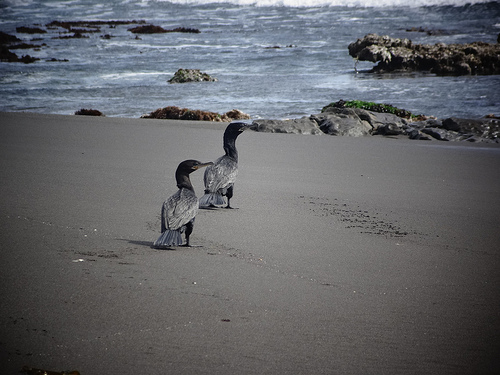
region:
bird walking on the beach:
[152, 160, 209, 250]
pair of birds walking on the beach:
[152, 120, 258, 250]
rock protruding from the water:
[167, 64, 217, 84]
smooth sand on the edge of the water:
[0, 107, 499, 373]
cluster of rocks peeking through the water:
[0, 18, 201, 66]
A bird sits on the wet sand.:
[201, 122, 253, 210]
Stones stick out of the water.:
[348, 33, 498, 75]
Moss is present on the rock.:
[323, 98, 426, 119]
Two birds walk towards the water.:
[152, 120, 253, 245]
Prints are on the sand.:
[301, 193, 406, 235]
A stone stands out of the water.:
[169, 68, 214, 83]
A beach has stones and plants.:
[1, 0, 498, 129]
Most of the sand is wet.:
[1, 112, 493, 373]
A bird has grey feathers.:
[156, 160, 212, 252]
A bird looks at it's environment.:
[155, 157, 215, 252]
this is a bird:
[143, 140, 211, 245]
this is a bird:
[191, 91, 267, 234]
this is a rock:
[325, 100, 405, 155]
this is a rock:
[152, 83, 239, 130]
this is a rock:
[265, 105, 377, 141]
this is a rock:
[145, 54, 221, 103]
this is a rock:
[333, 28, 493, 93]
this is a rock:
[270, 105, 317, 146]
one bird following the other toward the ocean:
[149, 92, 261, 254]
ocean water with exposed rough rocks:
[122, 2, 492, 147]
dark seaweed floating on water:
[3, 3, 209, 69]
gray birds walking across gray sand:
[9, 112, 491, 369]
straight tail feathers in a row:
[150, 227, 187, 249]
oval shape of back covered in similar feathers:
[160, 185, 200, 226]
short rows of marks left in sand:
[300, 185, 420, 245]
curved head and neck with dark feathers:
[175, 150, 200, 187]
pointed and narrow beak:
[192, 158, 215, 171]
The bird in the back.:
[148, 155, 212, 251]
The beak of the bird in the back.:
[194, 161, 211, 167]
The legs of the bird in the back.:
[171, 226, 190, 246]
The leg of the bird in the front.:
[222, 187, 232, 208]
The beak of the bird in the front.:
[242, 124, 254, 132]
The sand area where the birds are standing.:
[9, 114, 494, 373]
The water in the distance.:
[6, 2, 498, 137]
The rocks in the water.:
[16, 6, 475, 132]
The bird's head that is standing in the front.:
[220, 121, 252, 157]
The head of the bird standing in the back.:
[176, 154, 213, 189]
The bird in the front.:
[199, 118, 256, 208]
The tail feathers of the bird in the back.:
[150, 232, 190, 252]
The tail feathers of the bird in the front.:
[197, 191, 228, 210]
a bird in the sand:
[145, 140, 215, 250]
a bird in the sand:
[193, 98, 250, 212]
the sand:
[2, 106, 497, 372]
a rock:
[172, 64, 219, 91]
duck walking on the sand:
[132, 135, 207, 253]